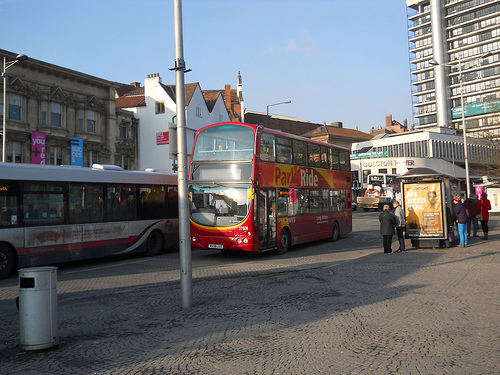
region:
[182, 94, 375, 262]
double decker bus on the road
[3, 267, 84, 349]
trash can on the sidewalk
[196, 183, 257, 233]
front window of a bus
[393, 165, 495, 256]
bus stop on the sidewalk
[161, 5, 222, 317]
pole in the sidewalk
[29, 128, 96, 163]
banners on a building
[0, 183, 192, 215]
windows on side of bus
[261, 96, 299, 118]
street light by the buildings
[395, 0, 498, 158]
buildings in the background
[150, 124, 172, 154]
street sign on a pole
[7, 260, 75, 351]
white trash can on street corner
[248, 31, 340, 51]
tiny spots of white cloud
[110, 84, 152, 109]
red roof on building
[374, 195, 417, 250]
people standing by the bus stop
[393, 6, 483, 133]
tall white and blue condo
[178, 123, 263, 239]
over sized tall clear window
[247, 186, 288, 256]
door on side of bus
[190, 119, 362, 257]
double decker red bus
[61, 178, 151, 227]
passengers standing in the bus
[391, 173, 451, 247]
yellow billboard on side of bus stop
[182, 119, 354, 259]
A red double decker bus on the road.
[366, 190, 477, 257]
People standing at the bus stop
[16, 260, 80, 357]
A white garbage can on sidewalk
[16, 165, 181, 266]
A passenger bus on the road.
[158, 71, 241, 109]
roof on the building.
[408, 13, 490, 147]
A tall apartment building with balcony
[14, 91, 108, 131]
Windows on the building.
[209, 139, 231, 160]
Person on the top level of bus.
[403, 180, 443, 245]
Poster sign on bus stop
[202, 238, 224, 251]
White license plate on the bus.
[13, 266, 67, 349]
trash can on the sidewalk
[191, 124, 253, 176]
window on top section of double decker bus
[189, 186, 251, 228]
windshield on bus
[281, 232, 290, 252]
tire on the bus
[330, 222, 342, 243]
tire on double decker bus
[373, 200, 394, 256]
person in front of bus stop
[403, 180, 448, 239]
sign on bus stop structure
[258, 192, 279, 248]
door on the bus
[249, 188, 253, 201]
side mirror on bus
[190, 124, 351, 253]
double decker bus on the street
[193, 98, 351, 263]
red passenger bus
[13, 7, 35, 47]
white clouds in blue sky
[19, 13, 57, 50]
white clouds in blue sky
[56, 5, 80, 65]
white clouds in blue sky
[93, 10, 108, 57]
white clouds in blue sky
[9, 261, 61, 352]
gray trash can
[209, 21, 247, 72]
white clouds in blue sky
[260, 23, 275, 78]
white clouds in blue sky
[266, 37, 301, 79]
white clouds in blue sky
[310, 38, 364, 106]
white clouds in blue sky